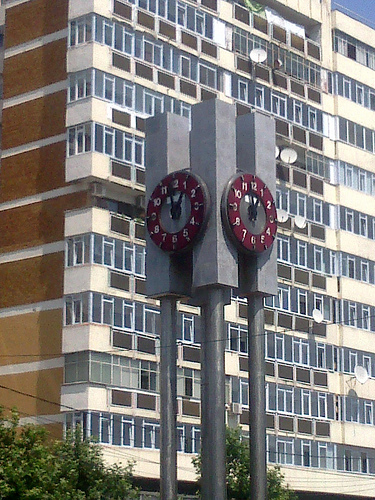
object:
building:
[0, 0, 375, 500]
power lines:
[1, 316, 373, 499]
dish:
[354, 366, 368, 384]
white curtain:
[73, 237, 83, 265]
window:
[91, 234, 115, 267]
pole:
[200, 290, 225, 500]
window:
[310, 107, 316, 130]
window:
[198, 60, 217, 89]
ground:
[323, 136, 337, 159]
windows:
[65, 13, 325, 182]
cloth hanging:
[273, 26, 286, 44]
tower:
[145, 98, 279, 500]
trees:
[0, 404, 299, 500]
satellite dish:
[250, 47, 267, 63]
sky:
[335, 0, 375, 22]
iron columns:
[160, 288, 265, 500]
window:
[104, 236, 113, 266]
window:
[124, 242, 133, 271]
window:
[105, 126, 114, 155]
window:
[123, 133, 133, 162]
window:
[104, 73, 114, 101]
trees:
[0, 404, 159, 500]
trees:
[190, 424, 297, 500]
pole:
[248, 296, 266, 500]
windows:
[91, 14, 219, 129]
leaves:
[44, 439, 87, 500]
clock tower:
[145, 98, 279, 297]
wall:
[67, 18, 224, 97]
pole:
[160, 298, 177, 500]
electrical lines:
[0, 316, 375, 500]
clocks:
[145, 168, 278, 254]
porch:
[232, 0, 323, 46]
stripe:
[0, 357, 65, 376]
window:
[63, 295, 82, 325]